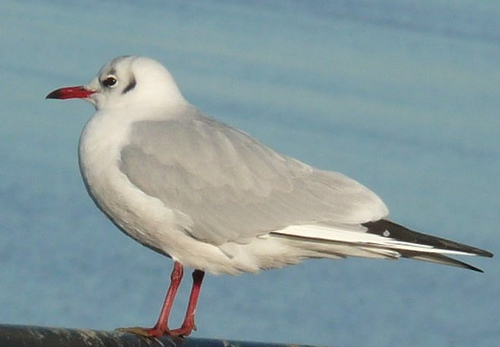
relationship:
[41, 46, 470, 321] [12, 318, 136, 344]
bird on rail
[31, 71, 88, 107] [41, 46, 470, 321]
beak of bird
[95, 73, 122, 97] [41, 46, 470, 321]
eye of bird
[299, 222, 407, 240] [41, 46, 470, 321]
feather of bird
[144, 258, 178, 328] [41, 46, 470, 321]
leg of bird